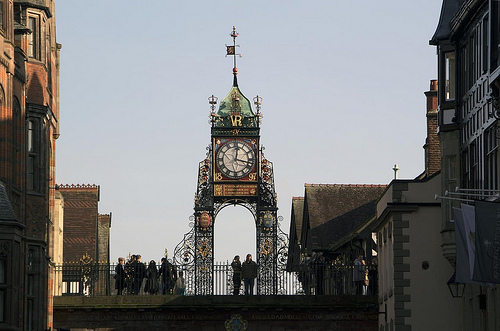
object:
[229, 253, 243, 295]
people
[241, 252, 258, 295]
people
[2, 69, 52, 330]
shadow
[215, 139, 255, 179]
clock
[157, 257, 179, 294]
people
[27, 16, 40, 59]
window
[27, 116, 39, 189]
window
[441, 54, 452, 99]
window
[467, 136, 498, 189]
window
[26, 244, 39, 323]
window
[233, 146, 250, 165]
black hands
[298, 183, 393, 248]
roof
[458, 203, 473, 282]
flag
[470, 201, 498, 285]
flag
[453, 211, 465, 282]
flag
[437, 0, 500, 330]
building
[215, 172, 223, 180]
number 18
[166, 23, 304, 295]
tower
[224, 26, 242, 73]
weather vane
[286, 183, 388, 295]
building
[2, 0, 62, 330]
building